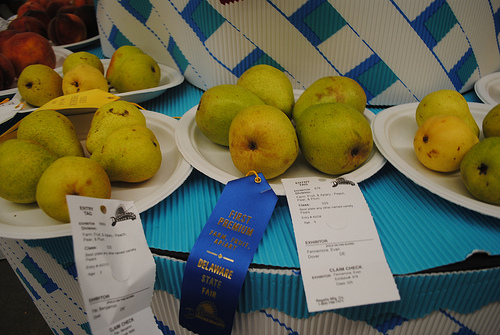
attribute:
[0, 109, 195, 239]
plate — white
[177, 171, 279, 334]
ribbon — blue, award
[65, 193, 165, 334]
tag — paper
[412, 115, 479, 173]
pear — yellow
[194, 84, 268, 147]
pear — arranged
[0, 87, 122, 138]
award — yellow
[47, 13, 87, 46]
peach — red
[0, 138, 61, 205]
pear — green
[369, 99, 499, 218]
plate — white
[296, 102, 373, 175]
pear — green